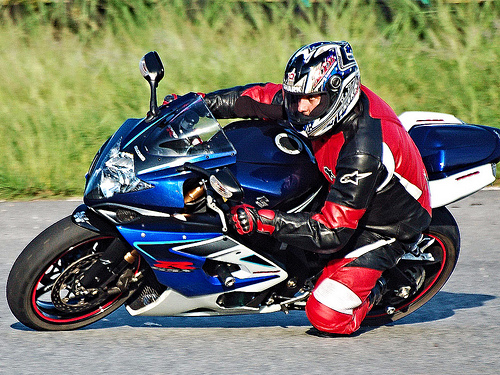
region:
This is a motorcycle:
[9, 25, 480, 371]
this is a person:
[165, 36, 449, 340]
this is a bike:
[13, 43, 498, 357]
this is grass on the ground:
[9, 69, 81, 195]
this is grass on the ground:
[37, 77, 88, 142]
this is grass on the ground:
[159, 13, 247, 81]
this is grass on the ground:
[379, 23, 454, 106]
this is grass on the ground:
[401, 48, 492, 135]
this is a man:
[286, 37, 431, 263]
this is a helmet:
[294, 35, 361, 111]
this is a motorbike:
[58, 109, 267, 332]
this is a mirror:
[140, 48, 165, 83]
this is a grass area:
[63, 36, 99, 137]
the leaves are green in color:
[42, 45, 73, 115]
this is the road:
[398, 324, 481, 371]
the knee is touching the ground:
[298, 292, 357, 354]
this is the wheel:
[20, 237, 96, 313]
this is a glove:
[228, 207, 258, 232]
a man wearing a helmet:
[258, 33, 427, 152]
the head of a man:
[250, 38, 368, 155]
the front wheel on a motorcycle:
[0, 133, 180, 327]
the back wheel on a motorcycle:
[330, 195, 488, 364]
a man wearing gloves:
[198, 187, 306, 269]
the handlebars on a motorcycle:
[163, 160, 278, 243]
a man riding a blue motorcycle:
[29, 70, 499, 333]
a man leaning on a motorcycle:
[67, 60, 442, 336]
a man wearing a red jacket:
[228, 38, 496, 365]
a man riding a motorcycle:
[16, 62, 475, 339]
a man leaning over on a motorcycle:
[31, 95, 476, 331]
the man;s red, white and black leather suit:
[304, 122, 423, 322]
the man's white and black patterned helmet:
[283, 40, 370, 137]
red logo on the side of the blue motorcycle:
[153, 257, 193, 280]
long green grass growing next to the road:
[23, 28, 100, 118]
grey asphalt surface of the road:
[195, 340, 270, 372]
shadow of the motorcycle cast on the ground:
[416, 276, 481, 338]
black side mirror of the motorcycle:
[139, 38, 170, 123]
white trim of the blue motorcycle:
[148, 240, 282, 322]